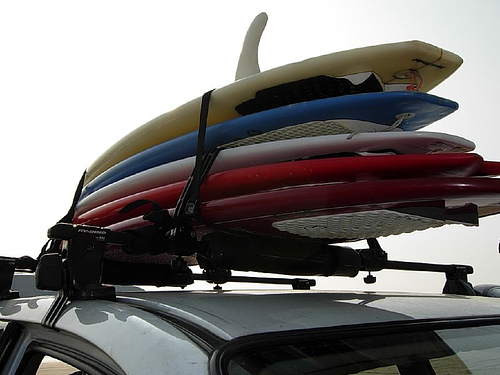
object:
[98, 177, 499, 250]
surfboards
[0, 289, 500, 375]
car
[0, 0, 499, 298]
sky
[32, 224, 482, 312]
rack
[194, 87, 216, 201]
strap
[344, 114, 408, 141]
string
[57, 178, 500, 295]
luggage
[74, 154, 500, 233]
objects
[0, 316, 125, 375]
door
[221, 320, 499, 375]
glass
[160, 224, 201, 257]
tube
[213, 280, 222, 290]
bolt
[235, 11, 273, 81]
fin